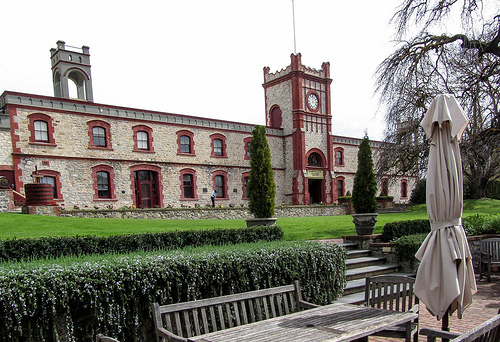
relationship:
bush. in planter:
[246, 124, 277, 218] [241, 217, 278, 225]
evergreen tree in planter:
[350, 126, 379, 211] [350, 212, 378, 233]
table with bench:
[187, 300, 418, 340] [153, 275, 322, 338]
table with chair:
[187, 300, 418, 340] [364, 272, 419, 339]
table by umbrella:
[187, 302, 418, 341] [412, 91, 472, 321]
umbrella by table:
[412, 91, 472, 321] [187, 302, 418, 341]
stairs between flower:
[334, 235, 400, 302] [0, 239, 347, 332]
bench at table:
[153, 275, 322, 338] [188, 295, 417, 337]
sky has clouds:
[0, 2, 496, 143] [90, 6, 265, 54]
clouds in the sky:
[90, 6, 265, 54] [0, 2, 496, 143]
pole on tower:
[292, 0, 297, 53] [264, 52, 335, 206]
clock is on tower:
[305, 92, 323, 112] [260, 56, 337, 204]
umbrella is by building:
[412, 91, 472, 321] [4, 53, 428, 213]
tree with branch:
[370, 0, 499, 201] [394, 0, 424, 36]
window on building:
[123, 158, 169, 212] [3, 2, 424, 222]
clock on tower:
[301, 89, 323, 114] [253, 60, 349, 209]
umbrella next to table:
[398, 91, 472, 322] [187, 300, 418, 340]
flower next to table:
[0, 239, 347, 332] [187, 300, 418, 340]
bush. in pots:
[246, 124, 277, 218] [240, 197, 402, 248]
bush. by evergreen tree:
[246, 124, 277, 218] [350, 127, 379, 214]